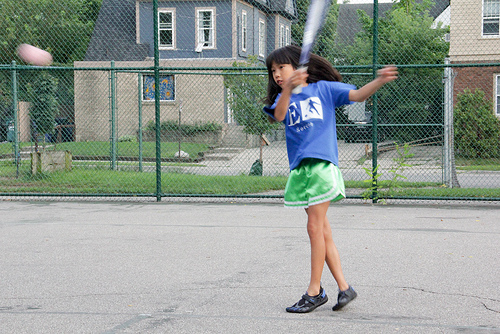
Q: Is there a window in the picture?
A: Yes, there is a window.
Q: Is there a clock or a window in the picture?
A: Yes, there is a window.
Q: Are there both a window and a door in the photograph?
A: No, there is a window but no doors.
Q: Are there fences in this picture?
A: Yes, there is a fence.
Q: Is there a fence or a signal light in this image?
A: Yes, there is a fence.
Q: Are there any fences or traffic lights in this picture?
A: Yes, there is a fence.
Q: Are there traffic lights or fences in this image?
A: Yes, there is a fence.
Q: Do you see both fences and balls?
A: Yes, there are both a fence and a ball.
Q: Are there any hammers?
A: No, there are no hammers.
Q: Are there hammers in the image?
A: No, there are no hammers.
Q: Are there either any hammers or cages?
A: No, there are no hammers or cages.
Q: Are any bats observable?
A: Yes, there is a bat.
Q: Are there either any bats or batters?
A: Yes, there is a bat.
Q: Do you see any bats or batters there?
A: Yes, there is a bat.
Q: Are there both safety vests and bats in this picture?
A: No, there is a bat but no safety jackets.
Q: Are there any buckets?
A: No, there are no buckets.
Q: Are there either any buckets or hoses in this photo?
A: No, there are no buckets or hoses.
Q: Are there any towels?
A: No, there are no towels.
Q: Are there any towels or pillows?
A: No, there are no towels or pillows.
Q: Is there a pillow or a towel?
A: No, there are no towels or pillows.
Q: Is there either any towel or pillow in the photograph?
A: No, there are no towels or pillows.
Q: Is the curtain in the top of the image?
A: Yes, the curtain is in the top of the image.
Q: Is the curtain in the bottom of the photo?
A: No, the curtain is in the top of the image.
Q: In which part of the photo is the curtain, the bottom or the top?
A: The curtain is in the top of the image.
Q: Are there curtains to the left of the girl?
A: Yes, there is a curtain to the left of the girl.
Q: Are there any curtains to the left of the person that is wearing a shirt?
A: Yes, there is a curtain to the left of the girl.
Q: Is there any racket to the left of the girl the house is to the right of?
A: No, there is a curtain to the left of the girl.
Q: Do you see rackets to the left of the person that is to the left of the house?
A: No, there is a curtain to the left of the girl.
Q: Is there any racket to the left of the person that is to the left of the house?
A: No, there is a curtain to the left of the girl.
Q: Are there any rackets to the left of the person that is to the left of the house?
A: No, there is a curtain to the left of the girl.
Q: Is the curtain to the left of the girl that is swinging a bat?
A: Yes, the curtain is to the left of the girl.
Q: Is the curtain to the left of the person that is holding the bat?
A: Yes, the curtain is to the left of the girl.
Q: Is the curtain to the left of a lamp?
A: No, the curtain is to the left of the girl.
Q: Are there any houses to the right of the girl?
A: Yes, there is a house to the right of the girl.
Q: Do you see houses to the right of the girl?
A: Yes, there is a house to the right of the girl.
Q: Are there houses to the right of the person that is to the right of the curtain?
A: Yes, there is a house to the right of the girl.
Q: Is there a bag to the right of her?
A: No, there is a house to the right of the girl.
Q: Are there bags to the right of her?
A: No, there is a house to the right of the girl.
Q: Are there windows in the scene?
A: Yes, there is a window.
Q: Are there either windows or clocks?
A: Yes, there is a window.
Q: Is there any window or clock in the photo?
A: Yes, there is a window.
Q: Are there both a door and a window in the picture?
A: No, there is a window but no doors.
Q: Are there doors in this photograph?
A: No, there are no doors.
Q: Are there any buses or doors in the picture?
A: No, there are no doors or buses.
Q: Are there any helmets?
A: No, there are no helmets.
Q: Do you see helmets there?
A: No, there are no helmets.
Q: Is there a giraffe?
A: No, there are no giraffes.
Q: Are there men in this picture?
A: No, there are no men.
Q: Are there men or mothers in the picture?
A: No, there are no men or mothers.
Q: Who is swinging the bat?
A: The girl is swinging the bat.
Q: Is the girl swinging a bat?
A: Yes, the girl is swinging a bat.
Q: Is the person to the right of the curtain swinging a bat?
A: Yes, the girl is swinging a bat.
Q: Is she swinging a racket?
A: No, the girl is swinging a bat.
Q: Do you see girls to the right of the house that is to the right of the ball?
A: Yes, there is a girl to the right of the house.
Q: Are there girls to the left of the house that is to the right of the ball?
A: No, the girl is to the right of the house.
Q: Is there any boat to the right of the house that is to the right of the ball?
A: No, there is a girl to the right of the house.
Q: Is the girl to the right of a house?
A: Yes, the girl is to the right of a house.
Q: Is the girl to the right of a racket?
A: No, the girl is to the right of a house.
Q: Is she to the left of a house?
A: No, the girl is to the right of a house.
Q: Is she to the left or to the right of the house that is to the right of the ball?
A: The girl is to the right of the house.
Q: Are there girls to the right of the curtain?
A: Yes, there is a girl to the right of the curtain.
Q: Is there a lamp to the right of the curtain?
A: No, there is a girl to the right of the curtain.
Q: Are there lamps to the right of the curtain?
A: No, there is a girl to the right of the curtain.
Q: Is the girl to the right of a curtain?
A: Yes, the girl is to the right of a curtain.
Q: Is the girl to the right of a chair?
A: No, the girl is to the right of a curtain.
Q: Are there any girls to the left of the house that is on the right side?
A: Yes, there is a girl to the left of the house.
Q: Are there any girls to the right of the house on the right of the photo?
A: No, the girl is to the left of the house.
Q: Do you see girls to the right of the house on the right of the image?
A: No, the girl is to the left of the house.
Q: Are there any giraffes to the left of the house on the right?
A: No, there is a girl to the left of the house.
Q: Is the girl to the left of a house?
A: Yes, the girl is to the left of a house.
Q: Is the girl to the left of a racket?
A: No, the girl is to the left of a house.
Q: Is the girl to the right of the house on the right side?
A: No, the girl is to the left of the house.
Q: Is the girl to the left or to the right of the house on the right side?
A: The girl is to the left of the house.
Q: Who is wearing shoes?
A: The girl is wearing shoes.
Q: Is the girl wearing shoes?
A: Yes, the girl is wearing shoes.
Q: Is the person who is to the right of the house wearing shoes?
A: Yes, the girl is wearing shoes.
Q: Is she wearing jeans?
A: No, the girl is wearing shoes.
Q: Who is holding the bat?
A: The girl is holding the bat.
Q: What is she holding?
A: The girl is holding the bat.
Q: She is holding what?
A: The girl is holding the bat.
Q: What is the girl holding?
A: The girl is holding the bat.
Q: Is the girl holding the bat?
A: Yes, the girl is holding the bat.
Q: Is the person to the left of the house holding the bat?
A: Yes, the girl is holding the bat.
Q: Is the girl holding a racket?
A: No, the girl is holding the bat.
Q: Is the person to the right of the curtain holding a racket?
A: No, the girl is holding the bat.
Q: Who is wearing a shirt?
A: The girl is wearing a shirt.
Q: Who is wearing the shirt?
A: The girl is wearing a shirt.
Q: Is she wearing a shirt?
A: Yes, the girl is wearing a shirt.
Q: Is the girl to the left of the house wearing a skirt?
A: No, the girl is wearing a shirt.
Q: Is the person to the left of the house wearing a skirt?
A: No, the girl is wearing a shirt.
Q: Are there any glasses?
A: No, there are no glasses.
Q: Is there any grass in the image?
A: Yes, there is grass.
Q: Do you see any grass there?
A: Yes, there is grass.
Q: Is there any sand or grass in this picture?
A: Yes, there is grass.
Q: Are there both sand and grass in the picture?
A: No, there is grass but no sand.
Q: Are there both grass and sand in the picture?
A: No, there is grass but no sand.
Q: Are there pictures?
A: No, there are no pictures.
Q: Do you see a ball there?
A: Yes, there is a ball.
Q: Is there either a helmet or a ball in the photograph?
A: Yes, there is a ball.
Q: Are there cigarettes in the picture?
A: No, there are no cigarettes.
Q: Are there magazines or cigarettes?
A: No, there are no cigarettes or magazines.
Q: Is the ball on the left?
A: Yes, the ball is on the left of the image.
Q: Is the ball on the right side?
A: No, the ball is on the left of the image.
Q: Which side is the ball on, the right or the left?
A: The ball is on the left of the image.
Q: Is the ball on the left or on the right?
A: The ball is on the left of the image.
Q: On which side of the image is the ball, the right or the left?
A: The ball is on the left of the image.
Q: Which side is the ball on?
A: The ball is on the left of the image.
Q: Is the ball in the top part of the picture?
A: Yes, the ball is in the top of the image.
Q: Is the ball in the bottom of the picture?
A: No, the ball is in the top of the image.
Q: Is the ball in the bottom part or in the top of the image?
A: The ball is in the top of the image.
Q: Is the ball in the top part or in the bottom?
A: The ball is in the top of the image.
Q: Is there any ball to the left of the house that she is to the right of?
A: Yes, there is a ball to the left of the house.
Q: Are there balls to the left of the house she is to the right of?
A: Yes, there is a ball to the left of the house.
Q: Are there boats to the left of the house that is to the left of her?
A: No, there is a ball to the left of the house.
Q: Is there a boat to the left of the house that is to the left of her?
A: No, there is a ball to the left of the house.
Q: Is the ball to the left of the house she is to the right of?
A: Yes, the ball is to the left of the house.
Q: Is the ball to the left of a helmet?
A: No, the ball is to the left of the house.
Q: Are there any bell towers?
A: No, there are no bell towers.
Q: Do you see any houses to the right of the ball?
A: Yes, there is a house to the right of the ball.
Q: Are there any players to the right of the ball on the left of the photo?
A: No, there is a house to the right of the ball.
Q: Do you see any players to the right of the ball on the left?
A: No, there is a house to the right of the ball.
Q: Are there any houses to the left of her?
A: Yes, there is a house to the left of the girl.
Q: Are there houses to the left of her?
A: Yes, there is a house to the left of the girl.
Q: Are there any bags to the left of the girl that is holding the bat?
A: No, there is a house to the left of the girl.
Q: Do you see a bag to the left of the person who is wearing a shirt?
A: No, there is a house to the left of the girl.